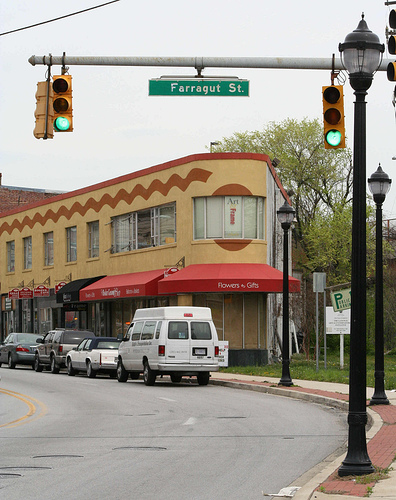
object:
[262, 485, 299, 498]
paper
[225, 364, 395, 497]
ground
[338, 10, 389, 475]
light post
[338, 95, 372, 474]
pole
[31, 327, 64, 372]
car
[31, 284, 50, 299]
red sign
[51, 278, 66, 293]
red sign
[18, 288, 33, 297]
red sign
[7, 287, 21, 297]
red sign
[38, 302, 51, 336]
door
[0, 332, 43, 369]
car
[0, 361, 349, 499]
pavement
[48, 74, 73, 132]
light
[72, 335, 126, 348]
top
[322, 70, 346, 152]
stoplight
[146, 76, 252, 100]
sign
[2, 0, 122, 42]
powerline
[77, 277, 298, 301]
awnings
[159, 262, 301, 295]
awning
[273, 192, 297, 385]
light post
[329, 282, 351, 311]
green sign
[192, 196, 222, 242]
window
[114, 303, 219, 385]
car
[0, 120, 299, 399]
building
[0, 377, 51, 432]
yellow lines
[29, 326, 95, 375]
suv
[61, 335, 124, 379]
car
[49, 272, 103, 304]
awning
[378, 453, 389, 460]
brick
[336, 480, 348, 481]
brick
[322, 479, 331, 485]
brick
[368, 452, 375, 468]
brick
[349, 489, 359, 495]
brick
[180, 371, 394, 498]
sidewalk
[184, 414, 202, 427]
line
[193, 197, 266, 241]
sign window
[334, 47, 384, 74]
light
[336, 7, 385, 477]
light pole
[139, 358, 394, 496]
curb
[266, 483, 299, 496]
paper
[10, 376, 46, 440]
line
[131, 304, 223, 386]
van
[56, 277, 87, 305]
canopy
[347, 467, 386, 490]
grass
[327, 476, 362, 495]
bricks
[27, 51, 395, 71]
pole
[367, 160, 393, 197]
fixture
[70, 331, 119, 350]
roof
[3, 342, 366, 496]
road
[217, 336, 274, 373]
wall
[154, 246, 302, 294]
sign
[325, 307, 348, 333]
lettering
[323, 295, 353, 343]
writing